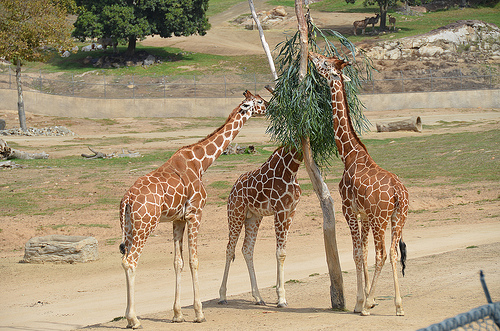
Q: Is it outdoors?
A: Yes, it is outdoors.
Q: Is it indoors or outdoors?
A: It is outdoors.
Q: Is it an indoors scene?
A: No, it is outdoors.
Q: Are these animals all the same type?
A: Yes, all the animals are giraffes.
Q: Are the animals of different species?
A: No, all the animals are giraffes.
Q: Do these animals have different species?
A: No, all the animals are giraffes.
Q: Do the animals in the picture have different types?
A: No, all the animals are giraffes.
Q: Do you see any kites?
A: No, there are no kites.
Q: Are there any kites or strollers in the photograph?
A: No, there are no kites or strollers.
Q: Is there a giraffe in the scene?
A: Yes, there are giraffes.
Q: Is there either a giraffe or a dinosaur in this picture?
A: Yes, there are giraffes.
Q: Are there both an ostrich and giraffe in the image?
A: No, there are giraffes but no ostriches.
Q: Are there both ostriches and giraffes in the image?
A: No, there are giraffes but no ostriches.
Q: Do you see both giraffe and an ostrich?
A: No, there are giraffes but no ostriches.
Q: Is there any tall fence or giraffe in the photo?
A: Yes, there are tall giraffes.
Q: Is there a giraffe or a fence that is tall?
A: Yes, the giraffes are tall.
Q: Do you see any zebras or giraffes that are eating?
A: Yes, the giraffes are eating.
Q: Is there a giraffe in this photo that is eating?
A: Yes, there are giraffes that are eating.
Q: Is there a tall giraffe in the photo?
A: Yes, there are tall giraffes.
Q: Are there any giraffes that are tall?
A: Yes, there are giraffes that are tall.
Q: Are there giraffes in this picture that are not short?
A: Yes, there are tall giraffes.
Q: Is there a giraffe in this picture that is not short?
A: Yes, there are tall giraffes.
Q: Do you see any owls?
A: No, there are no owls.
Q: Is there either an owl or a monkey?
A: No, there are no owls or monkeys.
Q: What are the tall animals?
A: The animals are giraffes.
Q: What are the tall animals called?
A: The animals are giraffes.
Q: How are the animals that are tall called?
A: The animals are giraffes.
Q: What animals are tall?
A: The animals are giraffes.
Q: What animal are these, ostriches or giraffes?
A: These are giraffes.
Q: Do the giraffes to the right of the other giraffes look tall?
A: Yes, the giraffes are tall.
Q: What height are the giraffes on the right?
A: The giraffes are tall.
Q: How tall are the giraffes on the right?
A: The giraffes are tall.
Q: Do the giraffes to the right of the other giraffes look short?
A: No, the giraffes are tall.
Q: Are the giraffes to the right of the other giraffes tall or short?
A: The giraffes are tall.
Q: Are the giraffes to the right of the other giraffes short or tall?
A: The giraffes are tall.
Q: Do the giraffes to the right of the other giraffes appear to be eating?
A: Yes, the giraffes are eating.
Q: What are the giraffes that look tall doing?
A: The giraffes are eating.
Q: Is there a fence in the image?
A: Yes, there is a fence.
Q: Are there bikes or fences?
A: Yes, there is a fence.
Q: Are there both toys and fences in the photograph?
A: No, there is a fence but no toys.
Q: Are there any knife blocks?
A: No, there are no knife blocks.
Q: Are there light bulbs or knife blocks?
A: No, there are no knife blocks or light bulbs.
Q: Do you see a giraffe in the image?
A: Yes, there are giraffes.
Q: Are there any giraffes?
A: Yes, there are giraffes.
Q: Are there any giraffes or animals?
A: Yes, there are giraffes.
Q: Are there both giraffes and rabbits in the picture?
A: No, there are giraffes but no rabbits.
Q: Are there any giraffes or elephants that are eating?
A: Yes, the giraffes are eating.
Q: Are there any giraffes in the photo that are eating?
A: Yes, there are giraffes that are eating.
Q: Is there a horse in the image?
A: No, there are no horses.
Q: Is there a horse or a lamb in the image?
A: No, there are no horses or lambs.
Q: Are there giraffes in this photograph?
A: Yes, there are giraffes.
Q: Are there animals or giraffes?
A: Yes, there are giraffes.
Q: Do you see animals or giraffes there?
A: Yes, there are giraffes.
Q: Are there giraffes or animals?
A: Yes, there are giraffes.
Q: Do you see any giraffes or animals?
A: Yes, there are giraffes.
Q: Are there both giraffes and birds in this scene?
A: No, there are giraffes but no birds.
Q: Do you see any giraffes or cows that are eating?
A: Yes, the giraffes are eating.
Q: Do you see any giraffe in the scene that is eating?
A: Yes, there are giraffes that are eating.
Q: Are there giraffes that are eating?
A: Yes, there are giraffes that are eating.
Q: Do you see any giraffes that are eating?
A: Yes, there are giraffes that are eating.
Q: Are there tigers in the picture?
A: No, there are no tigers.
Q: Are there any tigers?
A: No, there are no tigers.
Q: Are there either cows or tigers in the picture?
A: No, there are no tigers or cows.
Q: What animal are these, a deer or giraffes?
A: These are giraffes.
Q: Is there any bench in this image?
A: No, there are no benches.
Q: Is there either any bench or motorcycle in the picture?
A: No, there are no benches or motorcycles.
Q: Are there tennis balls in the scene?
A: No, there are no tennis balls.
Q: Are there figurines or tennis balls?
A: No, there are no tennis balls or figurines.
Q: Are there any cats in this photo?
A: No, there are no cats.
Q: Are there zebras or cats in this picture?
A: No, there are no cats or zebras.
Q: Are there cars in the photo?
A: No, there are no cars.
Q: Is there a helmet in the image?
A: No, there are no helmets.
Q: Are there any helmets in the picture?
A: No, there are no helmets.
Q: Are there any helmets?
A: No, there are no helmets.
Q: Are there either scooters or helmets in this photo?
A: No, there are no helmets or scooters.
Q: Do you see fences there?
A: Yes, there is a fence.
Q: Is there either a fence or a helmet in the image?
A: Yes, there is a fence.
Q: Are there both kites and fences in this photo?
A: No, there is a fence but no kites.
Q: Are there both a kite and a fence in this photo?
A: No, there is a fence but no kites.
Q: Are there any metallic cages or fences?
A: Yes, there is a metal fence.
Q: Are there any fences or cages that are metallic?
A: Yes, the fence is metallic.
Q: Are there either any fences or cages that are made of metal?
A: Yes, the fence is made of metal.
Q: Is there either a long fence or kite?
A: Yes, there is a long fence.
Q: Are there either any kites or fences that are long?
A: Yes, the fence is long.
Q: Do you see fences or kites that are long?
A: Yes, the fence is long.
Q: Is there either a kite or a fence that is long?
A: Yes, the fence is long.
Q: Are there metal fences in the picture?
A: Yes, there is a metal fence.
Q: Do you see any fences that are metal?
A: Yes, there is a metal fence.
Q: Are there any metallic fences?
A: Yes, there is a metal fence.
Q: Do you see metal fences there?
A: Yes, there is a metal fence.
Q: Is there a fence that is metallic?
A: Yes, there is a fence that is metallic.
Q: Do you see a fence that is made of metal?
A: Yes, there is a fence that is made of metal.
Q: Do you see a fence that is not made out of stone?
A: Yes, there is a fence that is made of metal.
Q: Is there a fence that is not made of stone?
A: Yes, there is a fence that is made of metal.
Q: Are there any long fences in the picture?
A: Yes, there is a long fence.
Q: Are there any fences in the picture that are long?
A: Yes, there is a fence that is long.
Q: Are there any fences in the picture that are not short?
A: Yes, there is a long fence.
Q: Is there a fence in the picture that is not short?
A: Yes, there is a long fence.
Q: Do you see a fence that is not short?
A: Yes, there is a long fence.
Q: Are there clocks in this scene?
A: No, there are no clocks.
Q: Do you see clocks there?
A: No, there are no clocks.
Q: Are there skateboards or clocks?
A: No, there are no clocks or skateboards.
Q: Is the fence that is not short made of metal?
A: Yes, the fence is made of metal.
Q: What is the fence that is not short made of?
A: The fence is made of metal.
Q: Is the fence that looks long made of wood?
A: No, the fence is made of metal.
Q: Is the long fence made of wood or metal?
A: The fence is made of metal.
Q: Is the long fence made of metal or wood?
A: The fence is made of metal.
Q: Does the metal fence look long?
A: Yes, the fence is long.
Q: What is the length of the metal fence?
A: The fence is long.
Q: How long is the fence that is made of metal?
A: The fence is long.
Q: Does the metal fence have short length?
A: No, the fence is long.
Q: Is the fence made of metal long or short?
A: The fence is long.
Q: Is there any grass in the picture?
A: Yes, there is grass.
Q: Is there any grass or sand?
A: Yes, there is grass.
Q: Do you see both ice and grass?
A: No, there is grass but no ice.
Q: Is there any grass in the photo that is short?
A: Yes, there is short grass.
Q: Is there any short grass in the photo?
A: Yes, there is short grass.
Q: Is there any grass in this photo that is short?
A: Yes, there is grass that is short.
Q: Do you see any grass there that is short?
A: Yes, there is grass that is short.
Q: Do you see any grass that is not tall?
A: Yes, there is short grass.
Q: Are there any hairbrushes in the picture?
A: No, there are no hairbrushes.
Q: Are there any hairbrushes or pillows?
A: No, there are no hairbrushes or pillows.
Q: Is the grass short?
A: Yes, the grass is short.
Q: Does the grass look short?
A: Yes, the grass is short.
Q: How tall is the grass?
A: The grass is short.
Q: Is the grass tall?
A: No, the grass is short.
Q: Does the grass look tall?
A: No, the grass is short.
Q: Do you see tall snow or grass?
A: No, there is grass but it is short.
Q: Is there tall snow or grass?
A: No, there is grass but it is short.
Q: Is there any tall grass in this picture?
A: No, there is grass but it is short.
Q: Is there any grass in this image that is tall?
A: No, there is grass but it is short.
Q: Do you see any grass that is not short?
A: No, there is grass but it is short.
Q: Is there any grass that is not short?
A: No, there is grass but it is short.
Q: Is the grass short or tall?
A: The grass is short.